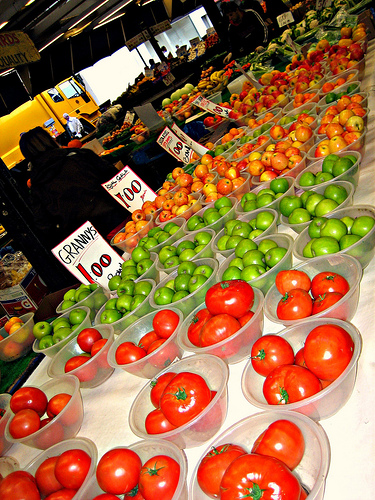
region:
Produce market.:
[0, 0, 373, 499]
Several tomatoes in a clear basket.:
[187, 406, 335, 499]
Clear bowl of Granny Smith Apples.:
[291, 202, 373, 278]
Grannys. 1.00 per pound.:
[48, 217, 126, 302]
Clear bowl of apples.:
[306, 115, 368, 166]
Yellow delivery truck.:
[0, 72, 102, 173]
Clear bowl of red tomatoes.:
[3, 374, 84, 452]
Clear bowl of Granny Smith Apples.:
[148, 256, 220, 317]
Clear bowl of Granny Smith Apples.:
[31, 306, 91, 360]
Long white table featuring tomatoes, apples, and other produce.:
[0, 27, 373, 498]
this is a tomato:
[201, 282, 254, 313]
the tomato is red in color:
[232, 464, 267, 477]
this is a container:
[328, 384, 351, 404]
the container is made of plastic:
[314, 383, 337, 408]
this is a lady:
[31, 133, 78, 188]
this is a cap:
[62, 111, 66, 115]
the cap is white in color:
[62, 111, 69, 114]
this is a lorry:
[51, 90, 94, 107]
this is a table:
[84, 395, 112, 426]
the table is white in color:
[334, 408, 368, 457]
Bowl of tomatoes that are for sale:
[243, 328, 358, 395]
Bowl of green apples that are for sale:
[214, 214, 282, 245]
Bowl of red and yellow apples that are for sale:
[244, 149, 303, 172]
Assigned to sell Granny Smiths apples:
[48, 222, 140, 297]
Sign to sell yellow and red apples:
[95, 159, 167, 214]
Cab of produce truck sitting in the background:
[47, 66, 101, 134]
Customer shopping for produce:
[16, 126, 103, 209]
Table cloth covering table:
[92, 390, 118, 429]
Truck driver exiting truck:
[61, 109, 86, 139]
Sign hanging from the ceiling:
[0, 20, 50, 73]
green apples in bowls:
[151, 187, 268, 287]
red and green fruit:
[125, 238, 277, 388]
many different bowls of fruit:
[118, 114, 329, 362]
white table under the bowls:
[96, 377, 124, 418]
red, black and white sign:
[56, 222, 134, 308]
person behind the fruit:
[22, 109, 102, 212]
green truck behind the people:
[35, 69, 110, 133]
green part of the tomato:
[272, 381, 295, 410]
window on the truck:
[57, 76, 90, 106]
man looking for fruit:
[207, 4, 265, 43]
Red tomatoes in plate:
[146, 376, 203, 429]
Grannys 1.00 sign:
[47, 217, 138, 295]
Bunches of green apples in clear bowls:
[107, 226, 361, 281]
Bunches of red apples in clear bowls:
[31, 328, 326, 495]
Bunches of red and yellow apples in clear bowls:
[112, 61, 373, 240]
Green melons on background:
[146, 88, 211, 105]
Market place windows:
[81, 25, 239, 70]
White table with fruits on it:
[95, 379, 148, 429]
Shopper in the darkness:
[20, 116, 125, 225]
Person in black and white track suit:
[227, 8, 278, 49]